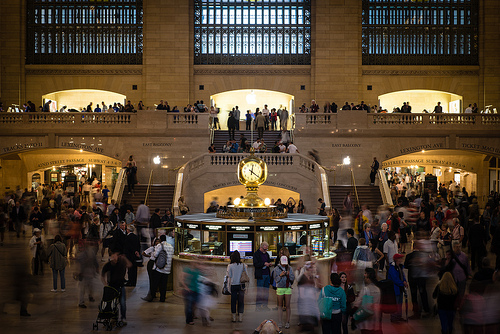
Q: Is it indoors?
A: Yes, it is indoors.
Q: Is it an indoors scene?
A: Yes, it is indoors.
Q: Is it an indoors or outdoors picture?
A: It is indoors.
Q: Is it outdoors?
A: No, it is indoors.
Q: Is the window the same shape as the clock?
A: No, the clock is round and the window is square.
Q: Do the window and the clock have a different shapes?
A: Yes, the window is round and the clock is square.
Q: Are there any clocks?
A: Yes, there is a clock.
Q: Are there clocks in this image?
A: Yes, there is a clock.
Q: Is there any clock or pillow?
A: Yes, there is a clock.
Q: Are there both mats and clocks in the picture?
A: No, there is a clock but no mats.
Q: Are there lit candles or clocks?
A: Yes, there is a lit clock.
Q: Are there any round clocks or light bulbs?
A: Yes, there is a round clock.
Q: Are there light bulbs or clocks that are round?
A: Yes, the clock is round.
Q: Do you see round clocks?
A: Yes, there is a round clock.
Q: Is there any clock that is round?
A: Yes, there is a clock that is round.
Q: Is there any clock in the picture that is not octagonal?
A: Yes, there is an round clock.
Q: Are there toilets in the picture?
A: No, there are no toilets.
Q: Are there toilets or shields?
A: No, there are no toilets or shields.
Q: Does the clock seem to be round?
A: Yes, the clock is round.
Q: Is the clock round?
A: Yes, the clock is round.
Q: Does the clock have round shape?
A: Yes, the clock is round.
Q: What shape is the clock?
A: The clock is round.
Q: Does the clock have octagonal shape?
A: No, the clock is round.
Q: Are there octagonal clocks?
A: No, there is a clock but it is round.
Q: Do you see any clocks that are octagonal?
A: No, there is a clock but it is round.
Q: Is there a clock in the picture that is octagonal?
A: No, there is a clock but it is round.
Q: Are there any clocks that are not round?
A: No, there is a clock but it is round.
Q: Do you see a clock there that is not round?
A: No, there is a clock but it is round.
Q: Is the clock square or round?
A: The clock is round.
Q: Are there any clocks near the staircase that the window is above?
A: Yes, there is a clock near the staircase.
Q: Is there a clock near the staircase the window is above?
A: Yes, there is a clock near the staircase.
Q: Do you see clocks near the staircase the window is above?
A: Yes, there is a clock near the staircase.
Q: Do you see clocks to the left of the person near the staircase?
A: Yes, there is a clock to the left of the person.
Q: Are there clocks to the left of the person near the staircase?
A: Yes, there is a clock to the left of the person.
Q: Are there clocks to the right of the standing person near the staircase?
A: No, the clock is to the left of the person.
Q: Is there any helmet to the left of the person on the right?
A: No, there is a clock to the left of the person.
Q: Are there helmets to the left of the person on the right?
A: No, there is a clock to the left of the person.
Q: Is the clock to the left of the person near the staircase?
A: Yes, the clock is to the left of the person.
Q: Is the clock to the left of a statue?
A: No, the clock is to the left of the person.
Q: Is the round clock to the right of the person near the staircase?
A: No, the clock is to the left of the person.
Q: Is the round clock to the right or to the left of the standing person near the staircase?
A: The clock is to the left of the person.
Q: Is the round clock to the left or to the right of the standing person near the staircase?
A: The clock is to the left of the person.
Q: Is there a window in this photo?
A: Yes, there is a window.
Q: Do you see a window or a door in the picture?
A: Yes, there is a window.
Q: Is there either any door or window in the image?
A: Yes, there is a window.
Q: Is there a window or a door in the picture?
A: Yes, there is a window.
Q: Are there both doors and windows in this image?
A: No, there is a window but no doors.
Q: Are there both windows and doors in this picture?
A: No, there is a window but no doors.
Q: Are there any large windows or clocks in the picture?
A: Yes, there is a large window.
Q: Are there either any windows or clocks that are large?
A: Yes, the window is large.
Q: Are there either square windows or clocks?
A: Yes, there is a square window.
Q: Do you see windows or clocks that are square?
A: Yes, the window is square.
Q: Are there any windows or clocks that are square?
A: Yes, the window is square.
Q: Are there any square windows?
A: Yes, there is a square window.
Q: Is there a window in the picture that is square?
A: Yes, there is a window that is square.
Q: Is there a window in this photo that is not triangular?
A: Yes, there is a square window.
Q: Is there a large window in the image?
A: Yes, there is a large window.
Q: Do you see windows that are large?
A: Yes, there is a window that is large.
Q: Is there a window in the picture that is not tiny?
A: Yes, there is a large window.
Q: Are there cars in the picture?
A: No, there are no cars.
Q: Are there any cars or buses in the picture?
A: No, there are no cars or buses.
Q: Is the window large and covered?
A: Yes, the window is large and covered.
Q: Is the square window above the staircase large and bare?
A: No, the window is large but covered.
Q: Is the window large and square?
A: Yes, the window is large and square.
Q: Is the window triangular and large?
A: No, the window is large but square.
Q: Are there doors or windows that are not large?
A: No, there is a window but it is large.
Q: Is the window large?
A: Yes, the window is large.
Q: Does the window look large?
A: Yes, the window is large.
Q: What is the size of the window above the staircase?
A: The window is large.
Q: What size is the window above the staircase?
A: The window is large.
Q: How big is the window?
A: The window is large.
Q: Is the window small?
A: No, the window is large.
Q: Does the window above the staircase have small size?
A: No, the window is large.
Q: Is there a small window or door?
A: No, there is a window but it is large.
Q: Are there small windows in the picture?
A: No, there is a window but it is large.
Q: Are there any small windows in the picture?
A: No, there is a window but it is large.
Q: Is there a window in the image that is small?
A: No, there is a window but it is large.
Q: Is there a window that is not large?
A: No, there is a window but it is large.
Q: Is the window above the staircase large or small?
A: The window is large.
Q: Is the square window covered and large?
A: Yes, the window is covered and large.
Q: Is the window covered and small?
A: No, the window is covered but large.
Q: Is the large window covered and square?
A: Yes, the window is covered and square.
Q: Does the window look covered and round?
A: No, the window is covered but square.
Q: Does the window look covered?
A: Yes, the window is covered.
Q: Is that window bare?
A: No, the window is covered.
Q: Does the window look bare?
A: No, the window is covered.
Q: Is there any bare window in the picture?
A: No, there is a window but it is covered.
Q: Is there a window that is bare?
A: No, there is a window but it is covered.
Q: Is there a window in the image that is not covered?
A: No, there is a window but it is covered.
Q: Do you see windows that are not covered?
A: No, there is a window but it is covered.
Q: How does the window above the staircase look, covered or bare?
A: The window is covered.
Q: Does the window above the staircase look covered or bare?
A: The window is covered.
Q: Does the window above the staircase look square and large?
A: Yes, the window is square and large.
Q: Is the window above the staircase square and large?
A: Yes, the window is square and large.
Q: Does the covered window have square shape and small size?
A: No, the window is square but large.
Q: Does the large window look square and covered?
A: Yes, the window is square and covered.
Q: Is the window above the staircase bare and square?
A: No, the window is square but covered.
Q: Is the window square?
A: Yes, the window is square.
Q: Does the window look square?
A: Yes, the window is square.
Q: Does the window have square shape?
A: Yes, the window is square.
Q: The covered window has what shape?
A: The window is square.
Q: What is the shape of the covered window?
A: The window is square.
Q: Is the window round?
A: No, the window is square.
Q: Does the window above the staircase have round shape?
A: No, the window is square.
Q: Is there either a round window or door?
A: No, there is a window but it is square.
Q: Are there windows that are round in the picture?
A: No, there is a window but it is square.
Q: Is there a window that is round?
A: No, there is a window but it is square.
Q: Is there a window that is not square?
A: No, there is a window but it is square.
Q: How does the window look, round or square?
A: The window is square.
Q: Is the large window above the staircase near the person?
A: Yes, the window is above the staircase.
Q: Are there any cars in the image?
A: No, there are no cars.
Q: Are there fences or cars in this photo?
A: No, there are no cars or fences.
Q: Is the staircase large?
A: Yes, the staircase is large.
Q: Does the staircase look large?
A: Yes, the staircase is large.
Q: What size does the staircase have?
A: The staircase has large size.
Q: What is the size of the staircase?
A: The staircase is large.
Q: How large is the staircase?
A: The staircase is large.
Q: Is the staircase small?
A: No, the staircase is large.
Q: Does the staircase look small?
A: No, the staircase is large.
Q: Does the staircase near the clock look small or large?
A: The staircase is large.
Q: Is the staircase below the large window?
A: Yes, the staircase is below the window.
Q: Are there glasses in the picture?
A: No, there are no glasses.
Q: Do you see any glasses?
A: No, there are no glasses.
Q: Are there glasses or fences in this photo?
A: No, there are no glasses or fences.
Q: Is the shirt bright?
A: Yes, the shirt is bright.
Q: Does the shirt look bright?
A: Yes, the shirt is bright.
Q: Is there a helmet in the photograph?
A: No, there are no helmets.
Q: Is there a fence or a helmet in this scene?
A: No, there are no helmets or fences.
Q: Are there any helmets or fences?
A: No, there are no helmets or fences.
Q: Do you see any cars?
A: No, there are no cars.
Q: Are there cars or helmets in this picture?
A: No, there are no cars or helmets.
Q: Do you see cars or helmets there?
A: No, there are no cars or helmets.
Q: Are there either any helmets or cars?
A: No, there are no cars or helmets.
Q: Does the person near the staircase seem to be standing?
A: Yes, the person is standing.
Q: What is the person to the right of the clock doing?
A: The person is standing.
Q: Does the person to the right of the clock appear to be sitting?
A: No, the person is standing.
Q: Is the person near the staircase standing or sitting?
A: The person is standing.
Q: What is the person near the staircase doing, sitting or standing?
A: The person is standing.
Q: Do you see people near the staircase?
A: Yes, there is a person near the staircase.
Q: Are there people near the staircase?
A: Yes, there is a person near the staircase.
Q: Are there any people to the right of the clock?
A: Yes, there is a person to the right of the clock.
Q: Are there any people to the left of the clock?
A: No, the person is to the right of the clock.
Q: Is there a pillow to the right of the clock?
A: No, there is a person to the right of the clock.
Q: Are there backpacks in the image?
A: Yes, there is a backpack.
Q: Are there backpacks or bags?
A: Yes, there is a backpack.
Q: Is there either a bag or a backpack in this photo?
A: Yes, there is a backpack.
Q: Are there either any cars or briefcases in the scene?
A: No, there are no cars or briefcases.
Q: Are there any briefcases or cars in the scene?
A: No, there are no cars or briefcases.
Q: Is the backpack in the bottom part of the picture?
A: Yes, the backpack is in the bottom of the image.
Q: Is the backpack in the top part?
A: No, the backpack is in the bottom of the image.